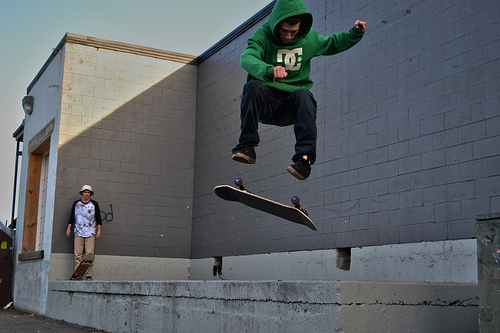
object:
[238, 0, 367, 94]
sweatshirt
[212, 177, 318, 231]
skateboard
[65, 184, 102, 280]
man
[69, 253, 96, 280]
skateboard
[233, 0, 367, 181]
man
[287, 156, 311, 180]
shoes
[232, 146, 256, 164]
shoes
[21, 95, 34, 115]
fixture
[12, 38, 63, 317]
wall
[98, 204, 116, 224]
graffiti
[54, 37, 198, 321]
wall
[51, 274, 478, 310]
floor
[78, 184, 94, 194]
hat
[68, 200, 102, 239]
shirt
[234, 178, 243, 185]
wheel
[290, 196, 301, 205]
wheel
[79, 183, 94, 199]
head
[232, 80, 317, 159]
pants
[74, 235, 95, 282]
pants